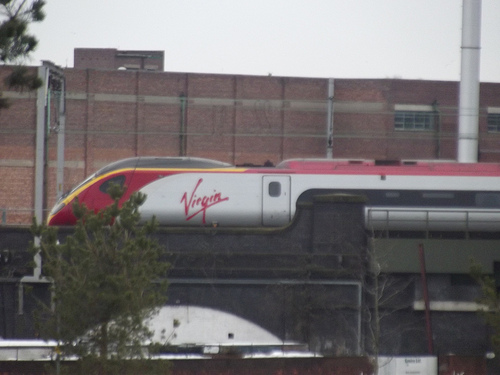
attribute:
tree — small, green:
[35, 201, 162, 367]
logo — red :
[180, 172, 235, 233]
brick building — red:
[80, 63, 308, 150]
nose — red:
[45, 156, 134, 228]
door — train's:
[262, 178, 292, 224]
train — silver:
[46, 157, 496, 229]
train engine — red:
[45, 151, 499, 237]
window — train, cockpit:
[97, 172, 129, 196]